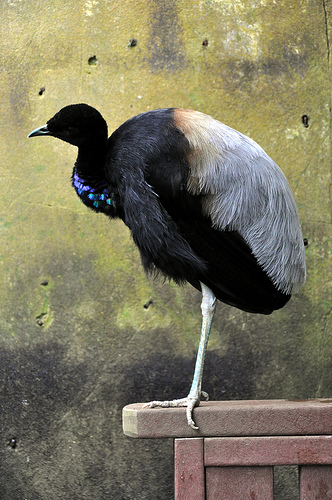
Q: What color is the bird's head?
A: Black.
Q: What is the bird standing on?
A: Rail.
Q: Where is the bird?
A: Standing on a rail.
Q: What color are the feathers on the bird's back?
A: White.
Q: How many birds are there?
A: 1.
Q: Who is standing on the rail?
A: Bird.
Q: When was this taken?
A: Daytime.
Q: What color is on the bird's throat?
A: Blue.